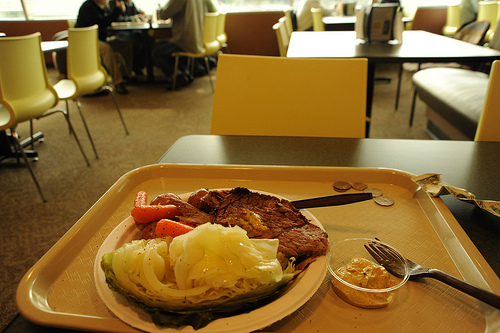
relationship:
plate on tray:
[93, 187, 333, 332] [11, 157, 498, 331]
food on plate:
[98, 186, 330, 332] [93, 187, 333, 332]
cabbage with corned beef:
[99, 221, 301, 331] [172, 187, 330, 274]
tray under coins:
[11, 157, 498, 331] [332, 179, 393, 206]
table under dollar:
[2, 134, 499, 333] [412, 171, 500, 215]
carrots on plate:
[132, 191, 194, 238] [93, 187, 333, 332]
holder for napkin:
[354, 5, 370, 41] [356, 9, 363, 39]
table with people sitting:
[107, 15, 171, 86] [73, 0, 220, 94]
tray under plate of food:
[11, 157, 498, 331] [93, 187, 333, 332]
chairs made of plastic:
[1, 24, 130, 202] [0, 25, 108, 131]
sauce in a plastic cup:
[331, 256, 395, 306] [326, 236, 411, 308]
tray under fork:
[11, 157, 498, 331] [365, 236, 500, 310]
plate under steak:
[93, 187, 333, 332] [172, 187, 330, 274]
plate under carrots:
[93, 187, 333, 332] [132, 191, 194, 238]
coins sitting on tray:
[332, 179, 393, 206] [11, 157, 498, 331]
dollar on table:
[412, 171, 500, 215] [2, 134, 499, 333]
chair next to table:
[213, 55, 368, 137] [2, 134, 499, 333]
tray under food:
[11, 157, 498, 331] [98, 186, 330, 332]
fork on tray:
[365, 236, 500, 310] [11, 157, 498, 331]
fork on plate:
[291, 191, 373, 210] [93, 187, 333, 332]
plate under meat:
[93, 187, 333, 332] [172, 187, 330, 274]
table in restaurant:
[2, 134, 499, 333] [2, 1, 500, 331]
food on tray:
[98, 186, 330, 332] [11, 157, 498, 331]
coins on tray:
[332, 179, 393, 206] [11, 157, 498, 331]